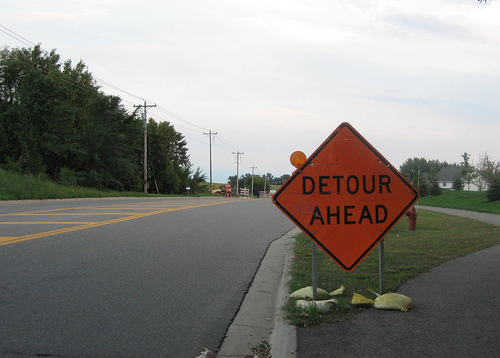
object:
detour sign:
[270, 121, 421, 273]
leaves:
[22, 117, 77, 140]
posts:
[310, 240, 386, 299]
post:
[310, 242, 322, 301]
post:
[377, 238, 387, 294]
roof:
[435, 162, 487, 184]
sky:
[0, 2, 496, 97]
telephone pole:
[127, 93, 159, 194]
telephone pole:
[225, 147, 245, 193]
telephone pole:
[245, 160, 259, 195]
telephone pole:
[260, 170, 276, 196]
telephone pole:
[204, 126, 218, 191]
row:
[138, 95, 274, 197]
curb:
[271, 233, 300, 355]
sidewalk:
[301, 205, 499, 352]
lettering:
[301, 167, 395, 227]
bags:
[295, 296, 337, 313]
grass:
[379, 226, 489, 276]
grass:
[303, 224, 430, 285]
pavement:
[120, 235, 228, 352]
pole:
[137, 100, 187, 196]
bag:
[349, 289, 417, 314]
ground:
[8, 313, 498, 355]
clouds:
[387, 23, 477, 82]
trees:
[0, 65, 109, 180]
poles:
[138, 95, 215, 195]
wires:
[149, 99, 209, 134]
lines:
[15, 201, 187, 239]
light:
[287, 150, 309, 170]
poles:
[310, 240, 387, 295]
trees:
[447, 159, 471, 193]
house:
[433, 165, 490, 192]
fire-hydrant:
[403, 203, 417, 230]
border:
[213, 265, 266, 355]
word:
[299, 170, 392, 197]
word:
[307, 203, 390, 226]